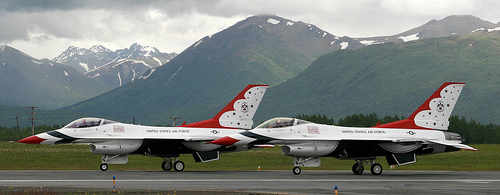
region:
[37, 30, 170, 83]
white clouds in blue sky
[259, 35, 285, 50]
white clouds in blue sky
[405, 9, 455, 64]
white clouds in blue sky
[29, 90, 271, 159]
jet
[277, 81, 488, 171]
jet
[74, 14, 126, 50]
white clouds in blue sky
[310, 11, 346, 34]
white clouds in blue sky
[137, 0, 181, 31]
white clouds in blue sky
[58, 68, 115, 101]
white clouds in blue sky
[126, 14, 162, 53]
white clouds in blue sky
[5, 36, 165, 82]
the tops of a mountains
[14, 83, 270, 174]
a red, white, and blue jet plane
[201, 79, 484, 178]
a red, white, and blue jet plane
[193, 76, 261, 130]
the tail of a jet plane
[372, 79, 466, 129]
the tail of a jet plane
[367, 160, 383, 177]
the landing gear of a jet plane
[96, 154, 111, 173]
the landing gear of a jet plane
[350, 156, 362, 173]
the landing gear of a jet plane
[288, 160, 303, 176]
the landing gear of a jet plane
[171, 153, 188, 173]
the landing gear of a jet plane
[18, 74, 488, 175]
Two airplanes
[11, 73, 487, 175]
These are jet airplanes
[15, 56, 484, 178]
The jets are owned by the U.S. Air Force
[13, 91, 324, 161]
There are men in both jets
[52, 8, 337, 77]
The mountains have some snow on them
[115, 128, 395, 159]
There are no windows on the sides of the jets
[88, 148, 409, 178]
The jets are parked on concrete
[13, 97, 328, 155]
The jet pilots are wearing helmets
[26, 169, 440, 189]
There is a white line on the runway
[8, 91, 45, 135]
Powerline posts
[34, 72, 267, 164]
red and white jet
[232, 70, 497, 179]
red and white jet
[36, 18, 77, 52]
white clouds in blue sky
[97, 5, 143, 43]
white clouds in blue sky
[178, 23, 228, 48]
white clouds in blue sky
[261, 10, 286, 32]
white clouds in blue sky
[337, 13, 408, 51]
white clouds in blue sky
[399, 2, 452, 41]
white clouds in blue sky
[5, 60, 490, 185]
white jets on gray ground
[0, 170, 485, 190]
white line dividing paved ground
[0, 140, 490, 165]
green grass behind planes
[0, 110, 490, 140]
line of trees with poles on one side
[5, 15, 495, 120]
green mountains in front of rocky mountains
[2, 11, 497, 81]
snow in lines and shapes over mountains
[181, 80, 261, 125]
dots over white curves on red tail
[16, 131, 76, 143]
red, white and blue angled stripes over nose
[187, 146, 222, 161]
angled poles containing dark object under plane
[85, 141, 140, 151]
sleek silver engine on side of jet